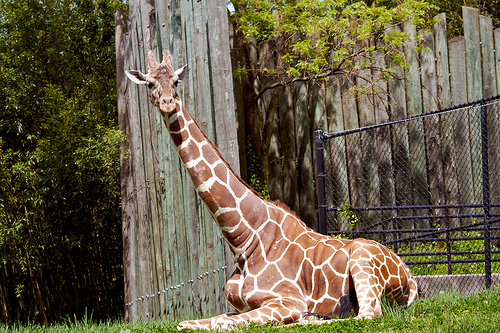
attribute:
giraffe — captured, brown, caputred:
[120, 43, 433, 329]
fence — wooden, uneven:
[113, 4, 497, 317]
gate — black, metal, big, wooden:
[305, 112, 499, 291]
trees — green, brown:
[0, 1, 349, 286]